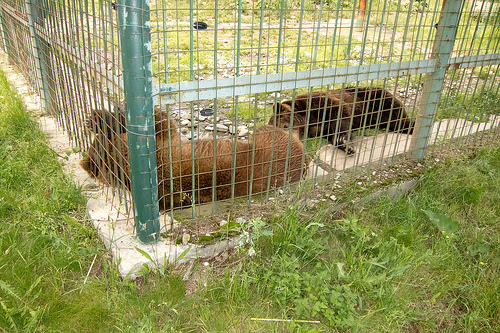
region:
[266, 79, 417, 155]
brown bear lying down on the ground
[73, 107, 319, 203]
brown bear lying down on the ground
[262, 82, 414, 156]
brown bear behind a fence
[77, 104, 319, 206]
brown bear behind a fence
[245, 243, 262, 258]
small white flower in the grass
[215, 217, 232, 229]
small white flower in the grass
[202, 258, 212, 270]
small white flower in the grass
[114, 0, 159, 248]
large metal pole painted green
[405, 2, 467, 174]
large metal pole painted green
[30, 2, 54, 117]
large metal pole painted green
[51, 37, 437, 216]
two brown bears in a cage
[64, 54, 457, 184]
two brown bears sleeping in a cage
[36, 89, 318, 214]
the light brown bear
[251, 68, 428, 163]
the dark brown bear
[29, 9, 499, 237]
green cage with two bears inside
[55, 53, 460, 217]
two bears laying on the ground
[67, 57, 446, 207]
two bears facing each other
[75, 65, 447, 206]
two bears in their cage sleeping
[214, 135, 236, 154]
metal square on cage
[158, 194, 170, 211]
metal square on cage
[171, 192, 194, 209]
metal square on cage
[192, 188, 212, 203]
metal square on cage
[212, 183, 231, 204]
metal square on cage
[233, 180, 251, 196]
metal square on cage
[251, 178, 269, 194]
metal square on cage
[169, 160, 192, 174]
metal square on cage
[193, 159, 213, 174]
metal square on cage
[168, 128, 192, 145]
metal square on cage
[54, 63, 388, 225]
bears in the pen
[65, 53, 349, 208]
the bears are laying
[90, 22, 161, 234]
green pole of pen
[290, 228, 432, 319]
the grass is overgrown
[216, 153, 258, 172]
the bear is brown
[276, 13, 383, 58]
dirt patches in grass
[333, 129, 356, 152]
paw of the bear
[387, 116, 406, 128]
paw of the bear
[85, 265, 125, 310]
dirt in the grass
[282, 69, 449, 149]
A brown dog in a cage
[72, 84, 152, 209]
A brown dog in a cage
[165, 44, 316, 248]
A blue cage wire wall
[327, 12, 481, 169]
A blue cage wire wall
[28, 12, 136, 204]
A blue cage wire wall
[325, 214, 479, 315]
A green vegitation ground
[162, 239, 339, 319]
A green vegitation ground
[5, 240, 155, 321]
A green vegitation ground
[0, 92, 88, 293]
A green vegitation ground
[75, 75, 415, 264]
a dog in a cage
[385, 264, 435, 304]
grass around the chair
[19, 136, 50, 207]
grass around the chair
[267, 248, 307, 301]
green weed by the brown bear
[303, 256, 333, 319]
green weed by the brown bear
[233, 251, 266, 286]
green weed by the brown bear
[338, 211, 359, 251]
green weed by the brown bear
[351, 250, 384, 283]
green weed by the brown bear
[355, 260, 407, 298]
green weed by the brown bear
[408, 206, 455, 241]
green weed by the brown bear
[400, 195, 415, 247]
green weed by the brown bear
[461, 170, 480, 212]
green weed by the brown bear